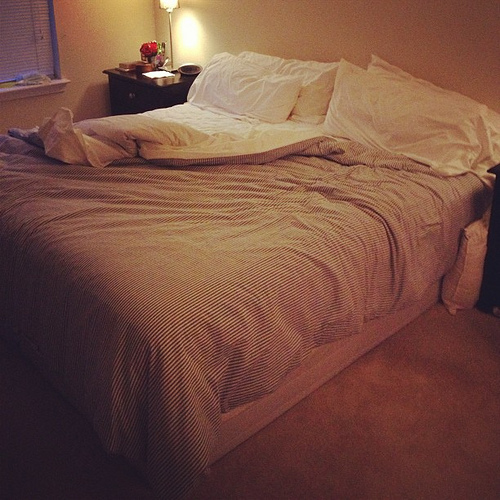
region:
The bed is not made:
[18, 55, 452, 400]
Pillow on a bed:
[326, 56, 482, 183]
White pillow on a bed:
[336, 60, 477, 166]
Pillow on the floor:
[458, 218, 486, 316]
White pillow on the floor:
[451, 212, 480, 322]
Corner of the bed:
[58, 256, 286, 496]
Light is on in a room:
[151, 1, 206, 52]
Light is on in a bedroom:
[156, 3, 218, 53]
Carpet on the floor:
[363, 370, 480, 480]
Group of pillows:
[216, 30, 458, 145]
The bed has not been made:
[11, 29, 458, 389]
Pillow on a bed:
[331, 58, 484, 170]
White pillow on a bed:
[329, 56, 478, 171]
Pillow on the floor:
[447, 220, 485, 317]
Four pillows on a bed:
[193, 36, 483, 174]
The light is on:
[154, 1, 196, 28]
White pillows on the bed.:
[194, 43, 486, 179]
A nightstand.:
[97, 58, 204, 128]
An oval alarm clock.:
[174, 58, 209, 83]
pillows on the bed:
[170, 40, 340, 146]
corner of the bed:
[86, 261, 250, 431]